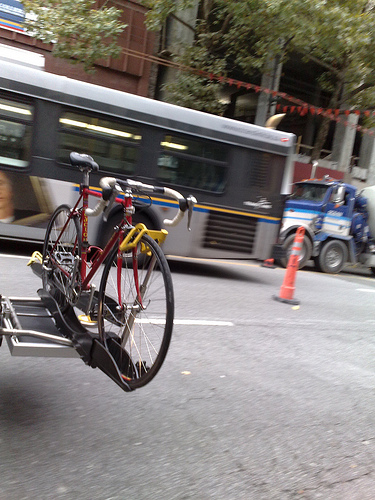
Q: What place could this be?
A: It is a pavement.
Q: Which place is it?
A: It is a pavement.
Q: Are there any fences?
A: No, there are no fences.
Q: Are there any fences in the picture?
A: No, there are no fences.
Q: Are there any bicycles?
A: Yes, there is a bicycle.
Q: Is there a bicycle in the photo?
A: Yes, there is a bicycle.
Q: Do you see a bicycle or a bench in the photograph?
A: Yes, there is a bicycle.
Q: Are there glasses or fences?
A: No, there are no fences or glasses.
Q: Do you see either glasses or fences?
A: No, there are no fences or glasses.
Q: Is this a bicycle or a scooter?
A: This is a bicycle.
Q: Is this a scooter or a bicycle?
A: This is a bicycle.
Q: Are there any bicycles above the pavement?
A: Yes, there is a bicycle above the pavement.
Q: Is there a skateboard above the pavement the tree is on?
A: No, there is a bicycle above the pavement.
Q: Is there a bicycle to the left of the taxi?
A: Yes, there is a bicycle to the left of the taxi.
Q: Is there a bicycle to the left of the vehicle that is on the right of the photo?
A: Yes, there is a bicycle to the left of the taxi.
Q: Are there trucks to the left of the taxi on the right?
A: No, there is a bicycle to the left of the taxi.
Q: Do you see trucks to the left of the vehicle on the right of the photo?
A: No, there is a bicycle to the left of the taxi.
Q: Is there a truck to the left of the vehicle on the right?
A: No, there is a bicycle to the left of the taxi.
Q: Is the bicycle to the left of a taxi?
A: Yes, the bicycle is to the left of a taxi.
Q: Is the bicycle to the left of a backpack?
A: No, the bicycle is to the left of a taxi.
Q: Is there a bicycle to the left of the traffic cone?
A: Yes, there is a bicycle to the left of the traffic cone.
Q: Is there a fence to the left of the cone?
A: No, there is a bicycle to the left of the cone.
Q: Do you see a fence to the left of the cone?
A: No, there is a bicycle to the left of the cone.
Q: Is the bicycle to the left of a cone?
A: Yes, the bicycle is to the left of a cone.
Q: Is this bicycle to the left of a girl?
A: No, the bicycle is to the left of a cone.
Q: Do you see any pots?
A: No, there are no pots.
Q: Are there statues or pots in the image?
A: No, there are no pots or statues.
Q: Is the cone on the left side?
A: No, the cone is on the right of the image.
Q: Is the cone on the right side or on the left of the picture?
A: The cone is on the right of the image.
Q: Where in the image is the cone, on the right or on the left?
A: The cone is on the right of the image.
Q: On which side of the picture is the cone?
A: The cone is on the right of the image.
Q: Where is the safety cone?
A: The safety cone is on the pavement.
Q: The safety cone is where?
A: The safety cone is on the pavement.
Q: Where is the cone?
A: The safety cone is on the pavement.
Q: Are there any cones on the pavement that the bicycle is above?
A: Yes, there is a cone on the pavement.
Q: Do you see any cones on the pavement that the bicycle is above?
A: Yes, there is a cone on the pavement.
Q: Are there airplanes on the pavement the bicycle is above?
A: No, there is a cone on the pavement.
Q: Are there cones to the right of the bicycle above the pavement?
A: Yes, there is a cone to the right of the bicycle.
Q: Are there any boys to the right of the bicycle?
A: No, there is a cone to the right of the bicycle.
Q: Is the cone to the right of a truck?
A: No, the cone is to the right of a bicycle.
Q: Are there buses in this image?
A: Yes, there is a bus.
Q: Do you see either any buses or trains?
A: Yes, there is a bus.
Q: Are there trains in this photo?
A: No, there are no trains.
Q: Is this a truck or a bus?
A: This is a bus.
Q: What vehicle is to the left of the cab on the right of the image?
A: The vehicle is a bus.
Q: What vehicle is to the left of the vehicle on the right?
A: The vehicle is a bus.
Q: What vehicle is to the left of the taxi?
A: The vehicle is a bus.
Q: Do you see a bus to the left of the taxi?
A: Yes, there is a bus to the left of the taxi.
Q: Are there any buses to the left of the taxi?
A: Yes, there is a bus to the left of the taxi.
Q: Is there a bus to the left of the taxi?
A: Yes, there is a bus to the left of the taxi.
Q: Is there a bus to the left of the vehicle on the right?
A: Yes, there is a bus to the left of the taxi.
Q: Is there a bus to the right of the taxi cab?
A: No, the bus is to the left of the taxi cab.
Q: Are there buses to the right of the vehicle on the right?
A: No, the bus is to the left of the taxi cab.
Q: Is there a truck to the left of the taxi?
A: No, there is a bus to the left of the taxi.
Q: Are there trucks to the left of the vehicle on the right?
A: No, there is a bus to the left of the taxi.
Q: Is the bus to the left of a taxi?
A: Yes, the bus is to the left of a taxi.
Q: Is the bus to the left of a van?
A: No, the bus is to the left of a taxi.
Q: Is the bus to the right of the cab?
A: No, the bus is to the left of the cab.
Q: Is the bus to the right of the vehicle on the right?
A: No, the bus is to the left of the cab.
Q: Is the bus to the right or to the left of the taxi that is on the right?
A: The bus is to the left of the cab.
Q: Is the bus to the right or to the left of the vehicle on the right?
A: The bus is to the left of the cab.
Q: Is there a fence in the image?
A: No, there are no fences.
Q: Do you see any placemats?
A: No, there are no placemats.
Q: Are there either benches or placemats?
A: No, there are no placemats or benches.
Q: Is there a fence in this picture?
A: No, there are no fences.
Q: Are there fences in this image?
A: No, there are no fences.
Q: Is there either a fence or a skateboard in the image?
A: No, there are no fences or skateboards.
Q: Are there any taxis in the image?
A: Yes, there is a taxi.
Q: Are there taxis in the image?
A: Yes, there is a taxi.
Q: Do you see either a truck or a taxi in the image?
A: Yes, there is a taxi.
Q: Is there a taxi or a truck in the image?
A: Yes, there is a taxi.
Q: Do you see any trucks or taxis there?
A: Yes, there is a taxi.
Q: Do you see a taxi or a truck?
A: Yes, there is a taxi.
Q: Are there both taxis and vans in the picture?
A: No, there is a taxi but no vans.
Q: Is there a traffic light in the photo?
A: No, there are no traffic lights.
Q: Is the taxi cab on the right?
A: Yes, the taxi cab is on the right of the image.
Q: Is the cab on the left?
A: No, the cab is on the right of the image.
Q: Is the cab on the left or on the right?
A: The cab is on the right of the image.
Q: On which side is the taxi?
A: The taxi is on the right of the image.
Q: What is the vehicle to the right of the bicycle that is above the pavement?
A: The vehicle is a taxi.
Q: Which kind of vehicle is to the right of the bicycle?
A: The vehicle is a taxi.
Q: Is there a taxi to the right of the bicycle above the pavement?
A: Yes, there is a taxi to the right of the bicycle.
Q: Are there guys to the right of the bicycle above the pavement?
A: No, there is a taxi to the right of the bicycle.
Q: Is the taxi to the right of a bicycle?
A: Yes, the taxi is to the right of a bicycle.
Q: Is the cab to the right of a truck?
A: No, the cab is to the right of a bicycle.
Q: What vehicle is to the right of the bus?
A: The vehicle is a taxi.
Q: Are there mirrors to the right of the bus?
A: No, there is a taxi to the right of the bus.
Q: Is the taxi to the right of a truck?
A: No, the taxi is to the right of the bus.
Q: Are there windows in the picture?
A: Yes, there are windows.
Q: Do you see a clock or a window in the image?
A: Yes, there are windows.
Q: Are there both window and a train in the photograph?
A: No, there are windows but no trains.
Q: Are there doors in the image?
A: No, there are no doors.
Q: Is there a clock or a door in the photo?
A: No, there are no doors or clocks.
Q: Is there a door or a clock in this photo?
A: No, there are no doors or clocks.